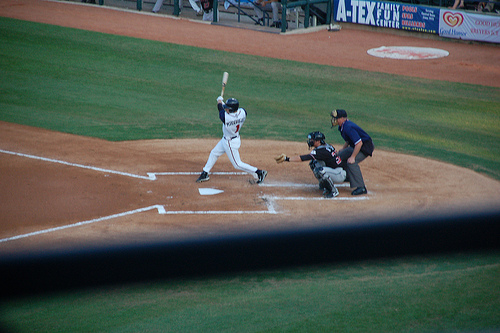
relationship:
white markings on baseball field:
[0, 140, 370, 243] [0, 15, 499, 331]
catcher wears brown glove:
[272, 131, 347, 199] [273, 154, 289, 165]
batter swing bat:
[195, 96, 268, 184] [220, 67, 229, 94]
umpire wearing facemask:
[328, 107, 375, 197] [327, 111, 337, 128]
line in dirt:
[0, 147, 157, 177] [2, 119, 499, 249]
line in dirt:
[3, 195, 159, 246] [2, 119, 499, 249]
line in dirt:
[145, 167, 252, 180] [2, 119, 499, 249]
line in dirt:
[155, 202, 275, 216] [2, 119, 499, 249]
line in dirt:
[257, 191, 365, 202] [2, 119, 499, 249]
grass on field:
[1, 14, 496, 331] [2, 13, 495, 332]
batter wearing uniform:
[195, 96, 268, 184] [195, 97, 272, 179]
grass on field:
[401, 87, 458, 124] [2, 13, 495, 332]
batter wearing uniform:
[187, 65, 273, 187] [202, 112, 258, 174]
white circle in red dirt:
[367, 41, 451, 63] [1, 0, 499, 89]